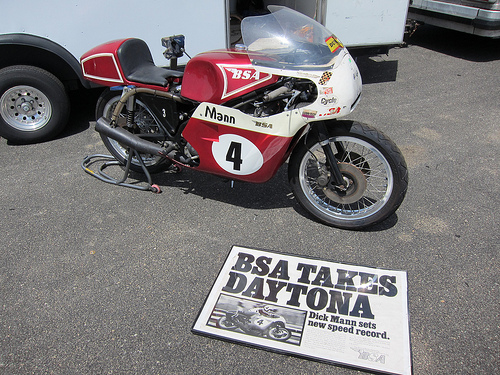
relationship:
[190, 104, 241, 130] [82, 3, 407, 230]
decal on bike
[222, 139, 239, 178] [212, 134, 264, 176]
4 on circle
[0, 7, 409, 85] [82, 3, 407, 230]
trailer behind bike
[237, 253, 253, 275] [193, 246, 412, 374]
letter on page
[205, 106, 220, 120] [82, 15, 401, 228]
letters on bike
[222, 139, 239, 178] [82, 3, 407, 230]
4 on bike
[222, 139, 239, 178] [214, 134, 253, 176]
4 in circle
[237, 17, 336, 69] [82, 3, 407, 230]
windshield of bike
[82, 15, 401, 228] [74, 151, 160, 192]
bike on stand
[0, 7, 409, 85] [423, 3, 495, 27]
trailer hooked to vehicle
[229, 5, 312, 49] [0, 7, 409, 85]
door of trailer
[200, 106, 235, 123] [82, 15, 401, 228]
mann on bike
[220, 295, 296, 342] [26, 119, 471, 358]
picture on ground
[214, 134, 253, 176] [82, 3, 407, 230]
circle on bike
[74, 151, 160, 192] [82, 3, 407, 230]
stand of bike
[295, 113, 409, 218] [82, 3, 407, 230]
tire of bike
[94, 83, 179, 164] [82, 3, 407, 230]
tire of bike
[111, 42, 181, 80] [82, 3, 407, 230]
seat of bike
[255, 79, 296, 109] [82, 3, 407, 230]
handle bars of bike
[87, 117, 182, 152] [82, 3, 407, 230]
tail pipe of bike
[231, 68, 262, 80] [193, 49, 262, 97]
bsa on tank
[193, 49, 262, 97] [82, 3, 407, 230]
tank of bike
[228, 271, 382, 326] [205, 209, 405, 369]
daytona on frame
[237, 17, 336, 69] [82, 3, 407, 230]
windshield on bike